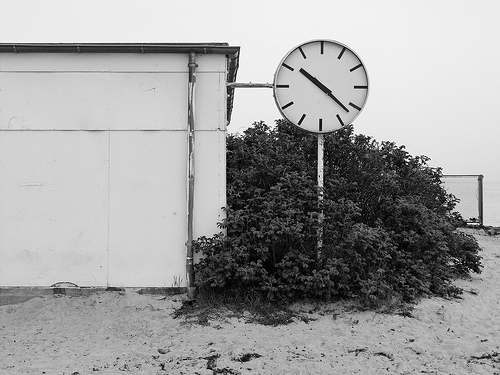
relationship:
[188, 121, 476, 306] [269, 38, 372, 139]
bush behind clock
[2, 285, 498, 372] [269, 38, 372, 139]
ground below clock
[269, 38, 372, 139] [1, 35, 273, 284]
clock near building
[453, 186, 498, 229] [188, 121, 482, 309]
water behind bush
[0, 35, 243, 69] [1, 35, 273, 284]
gutter on building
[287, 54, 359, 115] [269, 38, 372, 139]
numbers on clock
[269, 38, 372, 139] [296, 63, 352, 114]
clock has hands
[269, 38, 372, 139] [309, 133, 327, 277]
clock on pole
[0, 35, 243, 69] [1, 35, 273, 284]
gutter above building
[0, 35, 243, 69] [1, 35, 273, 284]
gutter on top of building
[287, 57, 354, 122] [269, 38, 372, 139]
face on clock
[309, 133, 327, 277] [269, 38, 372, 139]
pole on clock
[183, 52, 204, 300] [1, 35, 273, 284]
pipe on building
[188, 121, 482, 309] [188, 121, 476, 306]
bush behind bush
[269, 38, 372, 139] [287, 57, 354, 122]
clock has face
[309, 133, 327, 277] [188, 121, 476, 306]
pole in bush